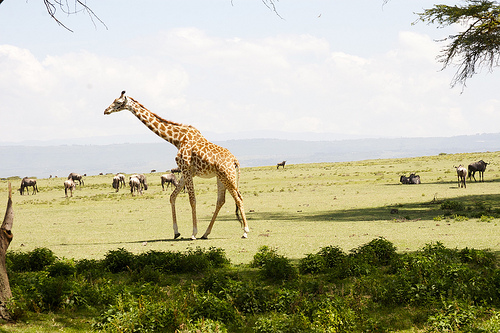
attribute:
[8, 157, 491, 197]
animal herd — small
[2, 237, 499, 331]
shrubs — small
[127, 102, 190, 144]
neck — long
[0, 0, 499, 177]
sky — blue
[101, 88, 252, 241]
giraffe — walking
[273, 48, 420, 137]
sky — white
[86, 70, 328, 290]
giraffe — white, brown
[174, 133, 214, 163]
spots — brown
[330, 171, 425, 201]
foothill — small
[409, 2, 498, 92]
leaves — green